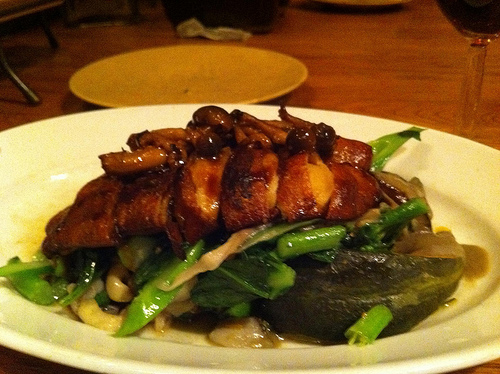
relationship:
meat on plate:
[61, 113, 361, 233] [0, 101, 500, 374]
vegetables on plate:
[10, 249, 202, 324] [0, 101, 500, 374]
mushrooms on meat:
[100, 96, 336, 171] [50, 164, 388, 244]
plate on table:
[56, 38, 309, 105] [8, 3, 498, 368]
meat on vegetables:
[41, 104, 381, 261] [104, 230, 285, 332]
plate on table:
[0, 101, 500, 374] [8, 3, 498, 368]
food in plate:
[6, 103, 482, 348] [0, 101, 500, 374]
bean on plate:
[114, 258, 185, 338] [9, 113, 485, 363]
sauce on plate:
[205, 310, 329, 354] [9, 113, 485, 363]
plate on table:
[69, 44, 310, 108] [13, 55, 490, 365]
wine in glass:
[438, 0, 499, 37] [442, 6, 491, 137]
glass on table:
[435, 3, 484, 161] [18, 20, 484, 372]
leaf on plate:
[8, 244, 75, 317] [2, 91, 480, 359]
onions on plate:
[52, 270, 152, 330] [2, 91, 480, 359]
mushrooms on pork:
[99, 103, 333, 179] [48, 163, 414, 240]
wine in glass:
[437, 2, 486, 38] [435, 10, 491, 135]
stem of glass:
[465, 39, 488, 89] [435, 10, 491, 135]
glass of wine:
[436, 0, 500, 139] [444, 4, 491, 57]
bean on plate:
[312, 300, 402, 345] [0, 101, 500, 374]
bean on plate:
[268, 228, 368, 265] [19, 102, 470, 371]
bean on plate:
[110, 272, 179, 339] [0, 101, 500, 374]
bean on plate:
[15, 249, 95, 323] [15, 103, 454, 328]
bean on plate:
[366, 132, 418, 159] [9, 113, 485, 363]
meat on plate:
[41, 104, 381, 261] [9, 113, 485, 363]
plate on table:
[9, 113, 485, 363] [13, 55, 490, 365]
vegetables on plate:
[0, 200, 428, 346] [0, 101, 500, 374]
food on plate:
[6, 103, 482, 348] [0, 101, 500, 374]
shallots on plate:
[149, 228, 256, 299] [0, 101, 500, 374]